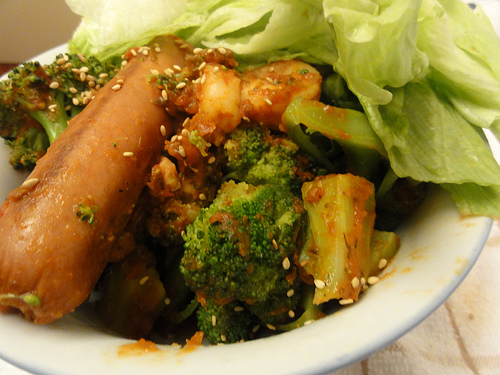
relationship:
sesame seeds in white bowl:
[338, 257, 390, 304] [0, 38, 500, 373]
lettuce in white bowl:
[52, 0, 499, 221] [0, 38, 500, 373]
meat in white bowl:
[2, 30, 192, 329] [0, 38, 500, 373]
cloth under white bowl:
[329, 223, 497, 373] [0, 38, 500, 373]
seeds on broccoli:
[208, 205, 270, 277] [179, 178, 306, 320]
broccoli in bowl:
[181, 186, 302, 304] [392, 213, 472, 308]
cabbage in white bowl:
[66, 1, 498, 214] [0, 38, 500, 373]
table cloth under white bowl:
[324, 221, 498, 374] [0, 38, 500, 373]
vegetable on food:
[197, 0, 499, 350] [0, 0, 499, 348]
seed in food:
[313, 277, 325, 290] [0, 0, 499, 365]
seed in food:
[337, 299, 353, 305] [0, 0, 499, 365]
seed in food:
[351, 278, 358, 290] [0, 0, 499, 365]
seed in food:
[367, 276, 377, 286] [0, 0, 499, 365]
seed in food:
[379, 260, 386, 269] [0, 0, 499, 365]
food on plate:
[55, 24, 420, 318] [13, 28, 447, 330]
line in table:
[445, 302, 477, 374] [321, 222, 498, 373]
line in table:
[359, 360, 370, 372] [321, 222, 498, 373]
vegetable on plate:
[17, 30, 423, 310] [400, 244, 461, 317]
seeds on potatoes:
[20, 38, 387, 373] [167, 58, 319, 151]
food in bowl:
[0, 0, 499, 365] [0, 1, 495, 371]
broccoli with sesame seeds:
[0, 42, 384, 345] [25, 43, 205, 113]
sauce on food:
[150, 41, 297, 163] [0, 0, 499, 365]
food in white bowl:
[0, 0, 499, 365] [0, 38, 500, 373]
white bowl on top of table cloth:
[0, 38, 500, 373] [324, 221, 498, 374]